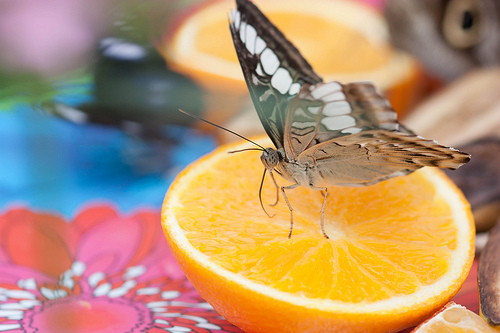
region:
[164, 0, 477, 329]
a butterfly on an orange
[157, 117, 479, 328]
it is an orange sliced inhalf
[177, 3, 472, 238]
the butterfly is gray and white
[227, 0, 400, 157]
the butterfly has white spots on the wings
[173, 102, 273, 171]
antennae of a butterfly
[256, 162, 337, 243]
the legs of a butterfly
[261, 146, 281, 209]
the proboscis of the butterfly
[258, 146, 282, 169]
dark spots on the butterfly's head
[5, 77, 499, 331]
a flowered patterned table cloth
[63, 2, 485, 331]
butterflies enjoying orange halves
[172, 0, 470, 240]
Butterfly on half an orange.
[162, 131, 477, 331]
Half an orange with butterfly on it.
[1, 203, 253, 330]
Flower decoration under orange.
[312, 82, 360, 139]
White spots on butterfly wings.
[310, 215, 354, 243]
White center of an orange.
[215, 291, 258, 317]
Part of an orange peel.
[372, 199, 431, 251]
Inside of an orange.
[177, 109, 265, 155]
Antennas of a butterfly.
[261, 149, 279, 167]
Small round head of a butterfly.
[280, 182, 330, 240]
Legs of a butterfly.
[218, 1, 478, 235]
a large butterfly standing on top of an orange slice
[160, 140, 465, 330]
half of an orange sliced in half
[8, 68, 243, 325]
a colorful table cloth underneath the orange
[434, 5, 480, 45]
a big eye looking at the butterfly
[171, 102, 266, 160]
the antenna of the butterfly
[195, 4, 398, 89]
another orange slice in the distance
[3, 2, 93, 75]
something purple in the corner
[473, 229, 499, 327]
something toasted by the corner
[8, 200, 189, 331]
a big pink flower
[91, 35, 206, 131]
something black sitting on the table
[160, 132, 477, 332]
The orange the butterfly is on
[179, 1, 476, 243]
the butterfly on the orange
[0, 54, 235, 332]
The floral patterned table cloth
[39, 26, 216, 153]
Black butterfly in the background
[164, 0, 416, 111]
Out of focus orange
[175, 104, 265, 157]
Antenna of the butterfly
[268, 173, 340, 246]
The butterflies legs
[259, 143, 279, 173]
The head of the butterfly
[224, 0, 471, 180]
The wings of the butterfly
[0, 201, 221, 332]
Pink flower on the tablecloth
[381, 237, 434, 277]
part of an orange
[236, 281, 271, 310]
outer cover of an orange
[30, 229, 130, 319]
drawing of a flower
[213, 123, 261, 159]
antennae of a butterfly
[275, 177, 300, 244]
leg of a butterfly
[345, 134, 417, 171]
wing of a butterfly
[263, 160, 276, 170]
head of the butterfly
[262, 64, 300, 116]
right wing of the butterfly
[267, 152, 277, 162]
eye of the butterfly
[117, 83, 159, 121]
part of a black wing